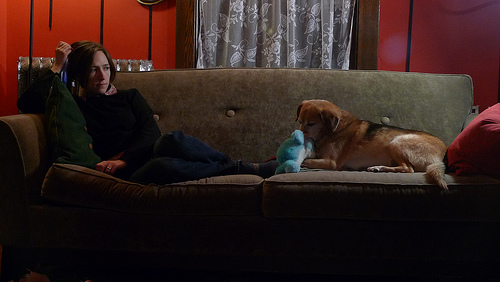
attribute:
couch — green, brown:
[2, 69, 499, 279]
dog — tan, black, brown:
[259, 100, 451, 190]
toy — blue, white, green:
[273, 130, 315, 173]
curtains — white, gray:
[193, 0, 353, 70]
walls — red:
[1, 0, 499, 117]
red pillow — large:
[445, 101, 499, 171]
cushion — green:
[39, 162, 263, 213]